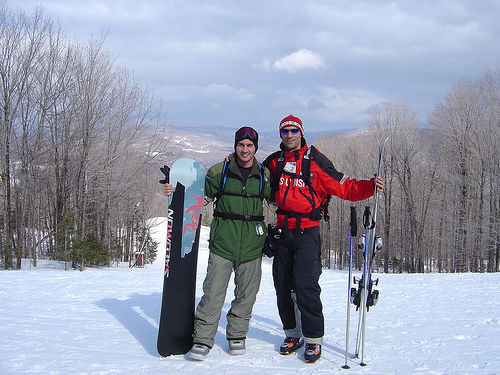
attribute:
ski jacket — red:
[259, 147, 368, 237]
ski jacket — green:
[205, 150, 267, 266]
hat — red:
[274, 112, 306, 132]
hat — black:
[234, 125, 260, 150]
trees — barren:
[11, 30, 161, 264]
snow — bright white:
[4, 266, 473, 372]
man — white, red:
[262, 119, 379, 369]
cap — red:
[276, 114, 306, 133]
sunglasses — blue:
[281, 125, 306, 134]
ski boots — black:
[276, 333, 332, 366]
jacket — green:
[206, 156, 268, 264]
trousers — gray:
[199, 256, 260, 349]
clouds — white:
[21, 8, 476, 151]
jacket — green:
[208, 157, 268, 256]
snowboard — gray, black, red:
[159, 151, 199, 362]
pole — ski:
[340, 206, 353, 373]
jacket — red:
[265, 149, 388, 228]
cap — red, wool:
[276, 110, 306, 126]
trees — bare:
[403, 89, 485, 268]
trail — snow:
[165, 212, 451, 371]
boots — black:
[283, 330, 326, 365]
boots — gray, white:
[184, 335, 265, 361]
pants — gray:
[188, 250, 265, 342]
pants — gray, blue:
[273, 230, 323, 350]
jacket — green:
[205, 158, 277, 260]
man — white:
[259, 113, 387, 353]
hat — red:
[278, 113, 306, 133]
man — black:
[264, 108, 401, 368]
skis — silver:
[355, 165, 385, 368]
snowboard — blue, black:
[155, 152, 213, 355]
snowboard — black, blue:
[157, 157, 209, 366]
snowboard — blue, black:
[157, 157, 217, 358]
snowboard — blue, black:
[155, 154, 207, 357]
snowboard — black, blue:
[153, 154, 211, 361]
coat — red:
[264, 146, 374, 242]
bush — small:
[68, 226, 109, 267]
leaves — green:
[73, 230, 114, 270]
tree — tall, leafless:
[2, 3, 62, 266]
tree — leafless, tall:
[364, 103, 414, 270]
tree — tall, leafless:
[430, 77, 491, 266]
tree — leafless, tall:
[37, 39, 129, 262]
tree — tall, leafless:
[461, 70, 497, 270]